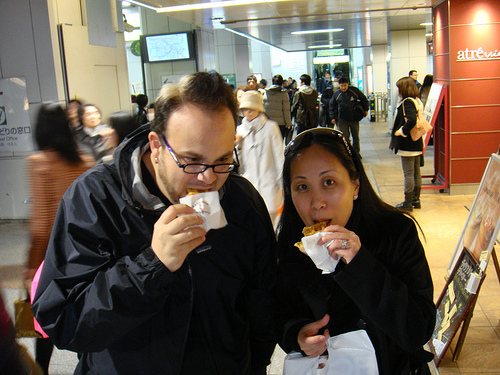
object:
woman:
[274, 124, 438, 363]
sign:
[450, 39, 498, 66]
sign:
[426, 149, 500, 366]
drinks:
[490, 209, 496, 220]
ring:
[340, 239, 347, 249]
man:
[27, 68, 286, 375]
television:
[138, 30, 195, 64]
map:
[145, 31, 192, 62]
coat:
[234, 112, 286, 235]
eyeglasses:
[156, 130, 240, 178]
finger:
[327, 238, 350, 255]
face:
[161, 105, 238, 207]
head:
[147, 67, 239, 213]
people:
[327, 76, 371, 163]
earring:
[353, 195, 358, 200]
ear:
[351, 173, 361, 201]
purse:
[401, 96, 432, 142]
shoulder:
[400, 98, 418, 119]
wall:
[0, 0, 427, 219]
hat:
[236, 87, 266, 114]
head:
[238, 89, 265, 123]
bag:
[322, 327, 382, 375]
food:
[293, 220, 345, 276]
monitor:
[139, 29, 194, 64]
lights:
[288, 27, 345, 36]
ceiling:
[219, 4, 435, 55]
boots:
[395, 189, 416, 211]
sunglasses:
[282, 126, 353, 156]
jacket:
[276, 201, 440, 375]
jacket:
[27, 121, 289, 375]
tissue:
[300, 230, 348, 276]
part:
[343, 242, 346, 246]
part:
[1, 90, 23, 127]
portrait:
[0, 73, 43, 225]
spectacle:
[65, 104, 79, 110]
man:
[63, 98, 84, 134]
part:
[354, 197, 356, 198]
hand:
[150, 202, 208, 273]